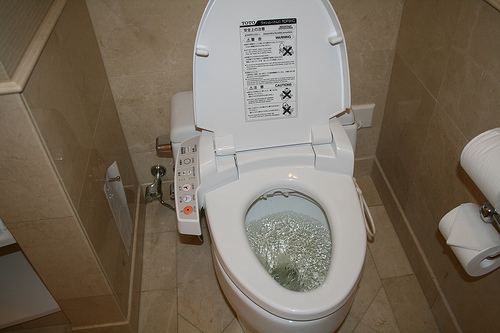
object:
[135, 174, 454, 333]
floor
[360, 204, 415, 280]
tiles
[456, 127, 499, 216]
tissue paper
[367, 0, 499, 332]
wall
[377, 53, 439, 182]
tiles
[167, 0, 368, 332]
toilet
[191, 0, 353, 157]
lid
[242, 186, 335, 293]
toilet sink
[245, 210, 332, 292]
water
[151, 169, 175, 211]
pipe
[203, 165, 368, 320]
bowl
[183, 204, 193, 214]
controls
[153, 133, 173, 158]
control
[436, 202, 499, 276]
toilet paper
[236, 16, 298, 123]
instructions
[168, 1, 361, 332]
toilet use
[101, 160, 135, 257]
bag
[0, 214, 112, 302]
tiles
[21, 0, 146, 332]
walls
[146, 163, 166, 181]
water valve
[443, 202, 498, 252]
end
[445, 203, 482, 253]
triangle